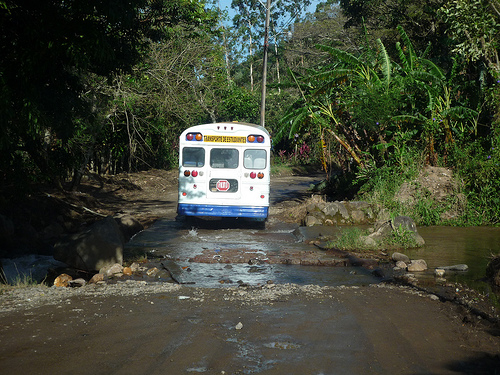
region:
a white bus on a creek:
[166, 113, 281, 230]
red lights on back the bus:
[181, 129, 267, 186]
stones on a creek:
[70, 232, 445, 374]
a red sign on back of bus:
[209, 175, 232, 195]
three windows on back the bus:
[176, 143, 268, 173]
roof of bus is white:
[174, 112, 270, 141]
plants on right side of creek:
[294, 0, 497, 216]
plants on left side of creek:
[6, 2, 160, 237]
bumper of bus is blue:
[171, 201, 271, 220]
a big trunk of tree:
[258, 3, 275, 123]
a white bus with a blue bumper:
[174, 120, 271, 227]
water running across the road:
[138, 220, 395, 285]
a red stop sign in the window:
[208, 190, 238, 191]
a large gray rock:
[52, 218, 124, 269]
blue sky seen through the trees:
[138, 2, 318, 81]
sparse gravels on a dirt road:
[3, 275, 440, 334]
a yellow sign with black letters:
[202, 133, 247, 143]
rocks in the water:
[353, 215, 432, 272]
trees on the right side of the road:
[274, 0, 496, 219]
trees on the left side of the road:
[3, 5, 329, 221]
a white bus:
[177, 120, 271, 232]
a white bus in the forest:
[31, 8, 488, 225]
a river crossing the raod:
[4, 218, 497, 290]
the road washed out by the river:
[120, 241, 384, 286]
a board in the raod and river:
[160, 255, 194, 281]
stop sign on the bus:
[214, 178, 231, 193]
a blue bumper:
[176, 203, 268, 220]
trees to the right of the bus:
[300, 41, 453, 190]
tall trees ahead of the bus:
[246, 3, 284, 130]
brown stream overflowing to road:
[5, 220, 490, 362]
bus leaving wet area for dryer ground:
[175, 110, 260, 210]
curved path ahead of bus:
[270, 140, 320, 200]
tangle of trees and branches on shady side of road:
[15, 10, 290, 225]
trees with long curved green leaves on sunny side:
[285, 15, 475, 170]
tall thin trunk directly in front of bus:
[255, 0, 270, 120]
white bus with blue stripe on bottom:
[175, 120, 265, 215]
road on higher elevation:
[25, 280, 470, 365]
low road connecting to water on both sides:
[115, 215, 425, 277]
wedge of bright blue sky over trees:
[207, 0, 317, 75]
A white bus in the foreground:
[162, 108, 278, 234]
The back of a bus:
[171, 113, 273, 239]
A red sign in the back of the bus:
[211, 174, 233, 197]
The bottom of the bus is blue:
[175, 193, 270, 220]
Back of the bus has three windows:
[180, 145, 268, 175]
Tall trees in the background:
[3, 3, 351, 167]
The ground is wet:
[1, 218, 490, 373]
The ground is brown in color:
[0, 225, 485, 372]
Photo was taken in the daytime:
[0, 3, 499, 373]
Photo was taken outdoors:
[4, 2, 493, 373]